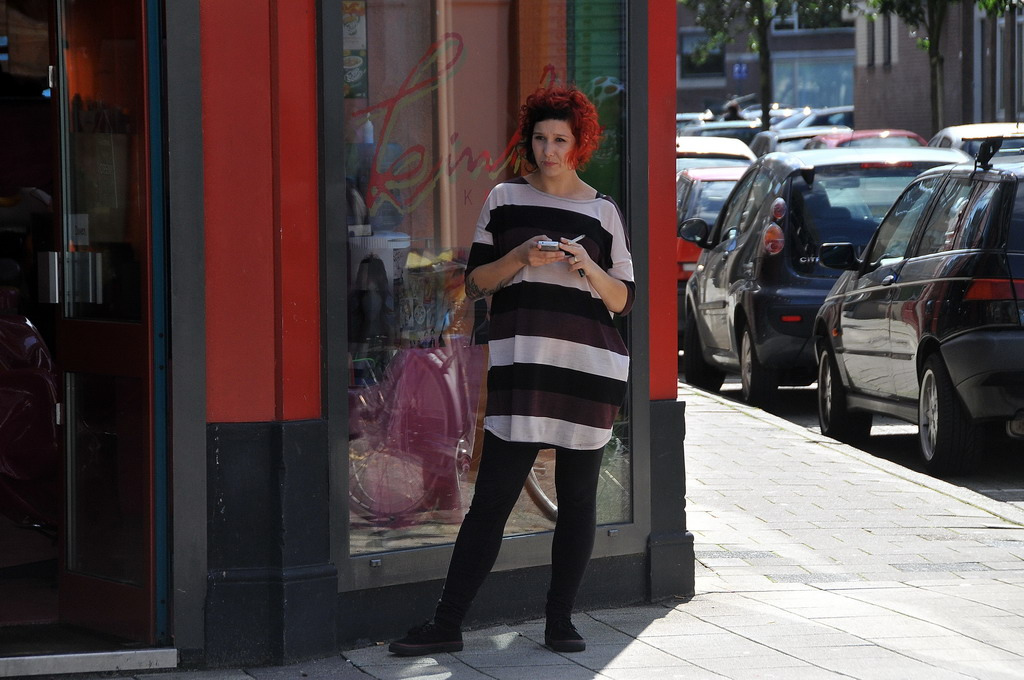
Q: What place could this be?
A: It is a sidewalk.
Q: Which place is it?
A: It is a sidewalk.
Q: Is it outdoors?
A: Yes, it is outdoors.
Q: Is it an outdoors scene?
A: Yes, it is outdoors.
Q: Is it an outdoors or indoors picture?
A: It is outdoors.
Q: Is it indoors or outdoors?
A: It is outdoors.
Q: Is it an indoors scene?
A: No, it is outdoors.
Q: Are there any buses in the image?
A: No, there are no buses.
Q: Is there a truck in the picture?
A: No, there are no trucks.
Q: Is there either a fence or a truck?
A: No, there are no trucks or fences.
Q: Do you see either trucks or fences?
A: No, there are no trucks or fences.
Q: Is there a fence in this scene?
A: No, there are no fences.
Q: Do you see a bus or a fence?
A: No, there are no fences or buses.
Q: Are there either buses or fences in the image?
A: No, there are no fences or buses.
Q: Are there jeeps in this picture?
A: No, there are no jeeps.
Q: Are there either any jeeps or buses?
A: No, there are no jeeps or buses.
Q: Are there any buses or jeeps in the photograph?
A: No, there are no jeeps or buses.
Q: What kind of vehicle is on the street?
A: The vehicle is a car.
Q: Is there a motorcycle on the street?
A: No, there is a car on the street.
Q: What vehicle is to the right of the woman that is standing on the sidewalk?
A: The vehicle is a car.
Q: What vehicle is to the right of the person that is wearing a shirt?
A: The vehicle is a car.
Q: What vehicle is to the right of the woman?
A: The vehicle is a car.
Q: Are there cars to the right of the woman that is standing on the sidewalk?
A: Yes, there is a car to the right of the woman.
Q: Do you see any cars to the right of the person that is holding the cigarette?
A: Yes, there is a car to the right of the woman.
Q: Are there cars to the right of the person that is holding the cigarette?
A: Yes, there is a car to the right of the woman.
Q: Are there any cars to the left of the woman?
A: No, the car is to the right of the woman.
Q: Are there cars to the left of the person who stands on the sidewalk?
A: No, the car is to the right of the woman.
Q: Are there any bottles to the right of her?
A: No, there is a car to the right of the woman.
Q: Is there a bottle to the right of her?
A: No, there is a car to the right of the woman.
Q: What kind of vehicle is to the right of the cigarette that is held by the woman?
A: The vehicle is a car.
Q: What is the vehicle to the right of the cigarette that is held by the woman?
A: The vehicle is a car.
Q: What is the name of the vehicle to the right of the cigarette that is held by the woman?
A: The vehicle is a car.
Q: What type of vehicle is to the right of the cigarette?
A: The vehicle is a car.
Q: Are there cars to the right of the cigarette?
A: Yes, there is a car to the right of the cigarette.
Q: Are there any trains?
A: No, there are no trains.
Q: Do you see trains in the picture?
A: No, there are no trains.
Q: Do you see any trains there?
A: No, there are no trains.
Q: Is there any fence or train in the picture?
A: No, there are no trains or fences.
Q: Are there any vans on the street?
A: No, there is a car on the street.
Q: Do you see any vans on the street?
A: No, there is a car on the street.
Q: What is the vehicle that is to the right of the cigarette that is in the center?
A: The vehicle is a car.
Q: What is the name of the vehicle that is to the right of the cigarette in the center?
A: The vehicle is a car.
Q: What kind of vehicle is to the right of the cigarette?
A: The vehicle is a car.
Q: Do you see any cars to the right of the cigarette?
A: Yes, there is a car to the right of the cigarette.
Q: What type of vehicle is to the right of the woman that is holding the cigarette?
A: The vehicle is a car.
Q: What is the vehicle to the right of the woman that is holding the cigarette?
A: The vehicle is a car.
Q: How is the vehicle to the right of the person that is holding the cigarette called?
A: The vehicle is a car.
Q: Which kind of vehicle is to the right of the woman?
A: The vehicle is a car.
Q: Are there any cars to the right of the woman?
A: Yes, there is a car to the right of the woman.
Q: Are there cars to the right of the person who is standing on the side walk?
A: Yes, there is a car to the right of the woman.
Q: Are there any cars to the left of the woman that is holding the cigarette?
A: No, the car is to the right of the woman.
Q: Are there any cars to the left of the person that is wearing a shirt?
A: No, the car is to the right of the woman.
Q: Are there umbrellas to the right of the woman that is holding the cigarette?
A: No, there is a car to the right of the woman.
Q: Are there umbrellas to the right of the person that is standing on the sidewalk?
A: No, there is a car to the right of the woman.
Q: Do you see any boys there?
A: No, there are no boys.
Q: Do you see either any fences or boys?
A: No, there are no boys or fences.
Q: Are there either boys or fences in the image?
A: No, there are no boys or fences.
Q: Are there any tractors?
A: No, there are no tractors.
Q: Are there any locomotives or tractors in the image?
A: No, there are no tractors or locomotives.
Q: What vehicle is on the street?
A: The vehicle is a car.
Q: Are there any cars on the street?
A: Yes, there is a car on the street.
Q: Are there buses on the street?
A: No, there is a car on the street.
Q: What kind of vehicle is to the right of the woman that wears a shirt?
A: The vehicle is a car.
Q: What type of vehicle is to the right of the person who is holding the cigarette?
A: The vehicle is a car.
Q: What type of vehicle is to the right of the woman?
A: The vehicle is a car.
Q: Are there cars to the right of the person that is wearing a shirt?
A: Yes, there is a car to the right of the woman.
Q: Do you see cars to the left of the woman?
A: No, the car is to the right of the woman.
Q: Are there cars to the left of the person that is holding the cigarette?
A: No, the car is to the right of the woman.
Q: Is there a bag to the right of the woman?
A: No, there is a car to the right of the woman.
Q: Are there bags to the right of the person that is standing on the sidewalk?
A: No, there is a car to the right of the woman.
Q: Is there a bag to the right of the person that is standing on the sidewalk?
A: No, there is a car to the right of the woman.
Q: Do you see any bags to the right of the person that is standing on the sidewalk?
A: No, there is a car to the right of the woman.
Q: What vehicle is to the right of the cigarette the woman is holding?
A: The vehicle is a car.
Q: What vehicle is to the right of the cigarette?
A: The vehicle is a car.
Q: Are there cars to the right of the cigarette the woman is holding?
A: Yes, there is a car to the right of the cigarette.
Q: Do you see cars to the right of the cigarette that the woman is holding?
A: Yes, there is a car to the right of the cigarette.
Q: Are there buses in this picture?
A: No, there are no buses.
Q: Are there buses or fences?
A: No, there are no buses or fences.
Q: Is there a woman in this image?
A: Yes, there is a woman.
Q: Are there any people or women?
A: Yes, there is a woman.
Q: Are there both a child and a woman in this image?
A: No, there is a woman but no children.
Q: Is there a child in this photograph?
A: No, there are no children.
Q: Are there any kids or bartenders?
A: No, there are no kids or bartenders.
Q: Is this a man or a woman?
A: This is a woman.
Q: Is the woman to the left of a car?
A: Yes, the woman is to the left of a car.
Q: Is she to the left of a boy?
A: No, the woman is to the left of a car.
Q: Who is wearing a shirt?
A: The woman is wearing a shirt.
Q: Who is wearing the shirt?
A: The woman is wearing a shirt.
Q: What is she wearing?
A: The woman is wearing a shirt.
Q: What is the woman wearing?
A: The woman is wearing a shirt.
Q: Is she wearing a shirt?
A: Yes, the woman is wearing a shirt.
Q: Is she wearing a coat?
A: No, the woman is wearing a shirt.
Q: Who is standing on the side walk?
A: The woman is standing on the side walk.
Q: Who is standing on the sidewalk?
A: The woman is standing on the side walk.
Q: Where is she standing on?
A: The woman is standing on the side walk.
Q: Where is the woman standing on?
A: The woman is standing on the side walk.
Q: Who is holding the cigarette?
A: The woman is holding the cigarette.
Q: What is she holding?
A: The woman is holding the cigarette.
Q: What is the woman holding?
A: The woman is holding the cigarette.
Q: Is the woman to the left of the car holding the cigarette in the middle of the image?
A: Yes, the woman is holding the cigarette.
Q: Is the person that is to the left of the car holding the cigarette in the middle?
A: Yes, the woman is holding the cigarette.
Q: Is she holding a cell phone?
A: No, the woman is holding the cigarette.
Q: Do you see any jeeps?
A: No, there are no jeeps.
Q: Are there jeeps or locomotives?
A: No, there are no jeeps or locomotives.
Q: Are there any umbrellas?
A: No, there are no umbrellas.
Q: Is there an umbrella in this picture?
A: No, there are no umbrellas.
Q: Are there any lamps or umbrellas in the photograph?
A: No, there are no umbrellas or lamps.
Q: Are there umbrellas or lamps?
A: No, there are no umbrellas or lamps.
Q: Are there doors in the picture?
A: Yes, there is a door.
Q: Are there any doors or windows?
A: Yes, there is a door.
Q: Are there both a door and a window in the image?
A: Yes, there are both a door and a window.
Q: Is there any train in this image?
A: No, there are no trains.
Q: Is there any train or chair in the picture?
A: No, there are no trains or chairs.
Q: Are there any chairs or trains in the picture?
A: No, there are no trains or chairs.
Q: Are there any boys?
A: No, there are no boys.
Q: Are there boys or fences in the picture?
A: No, there are no boys or fences.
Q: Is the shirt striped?
A: Yes, the shirt is striped.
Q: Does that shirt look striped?
A: Yes, the shirt is striped.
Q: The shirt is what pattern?
A: The shirt is striped.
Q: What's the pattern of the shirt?
A: The shirt is striped.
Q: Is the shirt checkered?
A: No, the shirt is striped.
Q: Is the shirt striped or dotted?
A: The shirt is striped.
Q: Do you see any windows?
A: Yes, there is a window.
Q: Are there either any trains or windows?
A: Yes, there is a window.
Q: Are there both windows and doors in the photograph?
A: Yes, there are both a window and a door.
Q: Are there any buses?
A: No, there are no buses.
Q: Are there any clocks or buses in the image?
A: No, there are no buses or clocks.